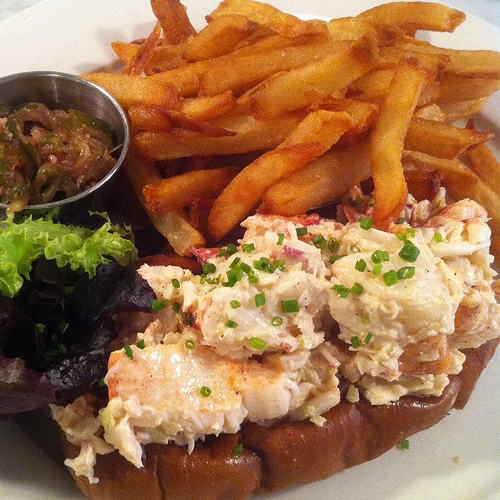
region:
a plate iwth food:
[108, 18, 475, 258]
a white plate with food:
[11, 1, 496, 468]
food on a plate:
[91, 11, 488, 362]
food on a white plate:
[7, 8, 487, 499]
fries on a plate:
[75, 7, 477, 244]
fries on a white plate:
[62, 7, 491, 224]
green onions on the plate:
[105, 156, 499, 441]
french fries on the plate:
[97, 2, 472, 229]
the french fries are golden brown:
[95, 0, 480, 229]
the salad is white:
[120, 203, 483, 423]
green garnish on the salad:
[162, 212, 435, 337]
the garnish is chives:
[147, 205, 459, 345]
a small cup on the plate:
[2, 55, 133, 226]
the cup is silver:
[3, 59, 145, 214]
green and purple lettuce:
[1, 210, 143, 397]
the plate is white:
[40, 2, 483, 494]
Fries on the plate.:
[116, 159, 471, 297]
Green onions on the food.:
[152, 202, 462, 381]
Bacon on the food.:
[150, 184, 400, 329]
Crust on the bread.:
[196, 358, 408, 499]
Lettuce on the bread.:
[1, 199, 213, 378]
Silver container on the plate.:
[7, 62, 127, 228]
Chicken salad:
[123, 158, 445, 462]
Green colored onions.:
[141, 233, 350, 345]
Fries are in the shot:
[13, 3, 498, 240]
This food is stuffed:
[38, 213, 499, 485]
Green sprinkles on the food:
[145, 208, 445, 392]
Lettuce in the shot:
[3, 147, 165, 442]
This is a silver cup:
[6, 64, 146, 229]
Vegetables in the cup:
[1, 67, 126, 217]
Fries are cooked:
[101, 8, 486, 233]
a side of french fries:
[121, 8, 426, 205]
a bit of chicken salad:
[194, 220, 432, 400]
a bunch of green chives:
[239, 278, 293, 334]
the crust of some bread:
[220, 442, 304, 489]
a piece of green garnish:
[16, 239, 159, 342]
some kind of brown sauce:
[3, 96, 86, 175]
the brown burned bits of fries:
[132, 29, 228, 138]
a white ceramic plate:
[418, 429, 484, 497]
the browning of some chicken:
[231, 341, 285, 388]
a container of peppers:
[0, 59, 140, 216]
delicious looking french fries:
[80, 1, 496, 252]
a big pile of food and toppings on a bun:
[33, 209, 498, 498]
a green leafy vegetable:
[1, 211, 146, 298]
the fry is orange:
[370, 61, 428, 226]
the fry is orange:
[413, 114, 490, 152]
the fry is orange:
[211, 116, 341, 239]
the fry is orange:
[147, 164, 237, 207]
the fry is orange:
[135, 164, 206, 256]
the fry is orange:
[87, 71, 180, 110]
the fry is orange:
[208, 1, 330, 38]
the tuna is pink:
[67, 194, 485, 473]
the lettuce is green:
[4, 211, 131, 295]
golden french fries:
[83, 1, 498, 245]